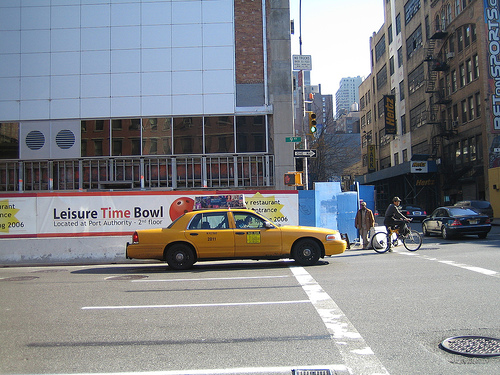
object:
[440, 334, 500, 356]
manhole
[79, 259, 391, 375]
crosswalk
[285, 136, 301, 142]
street sign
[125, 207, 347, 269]
cab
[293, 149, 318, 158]
sign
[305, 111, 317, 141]
light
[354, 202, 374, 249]
man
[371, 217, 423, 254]
bicycle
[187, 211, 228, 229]
rear window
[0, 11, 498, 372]
scene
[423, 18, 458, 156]
fire escape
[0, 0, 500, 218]
different buildings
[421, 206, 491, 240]
car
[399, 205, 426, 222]
car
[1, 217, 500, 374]
city street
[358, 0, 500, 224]
building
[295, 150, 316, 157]
one way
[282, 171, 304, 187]
crosswalk signal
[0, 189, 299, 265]
panel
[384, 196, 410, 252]
man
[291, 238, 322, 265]
wheel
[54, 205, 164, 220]
lettering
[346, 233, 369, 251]
corner